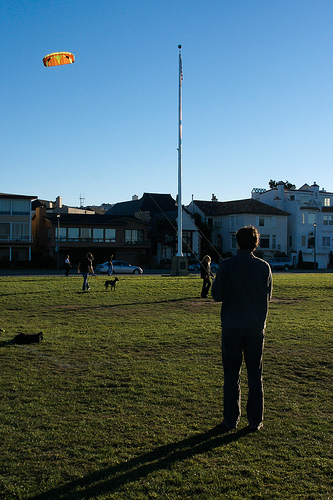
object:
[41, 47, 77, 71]
orange parachute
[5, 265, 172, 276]
color is on road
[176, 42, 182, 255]
white color pole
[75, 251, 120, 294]
man with dog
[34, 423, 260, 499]
shadow in the ground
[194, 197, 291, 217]
brown roof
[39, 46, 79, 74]
parachute is flying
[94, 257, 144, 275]
silver car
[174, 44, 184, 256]
tall flag pole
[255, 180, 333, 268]
house painted white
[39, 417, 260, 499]
shadow of legs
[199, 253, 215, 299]
person flying a kite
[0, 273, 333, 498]
field of grass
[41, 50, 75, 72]
flying a kite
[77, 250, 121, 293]
walking pet dog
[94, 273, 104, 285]
orange leash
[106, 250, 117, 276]
person walking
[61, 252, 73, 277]
person is walking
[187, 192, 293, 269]
white house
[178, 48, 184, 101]
american flag flat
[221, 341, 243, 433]
person's legs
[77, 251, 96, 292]
woman walking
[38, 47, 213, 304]
man flying a kite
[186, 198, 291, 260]
white apartment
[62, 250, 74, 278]
man walking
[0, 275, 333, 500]
freshly cut grass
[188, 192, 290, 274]
apartment buildings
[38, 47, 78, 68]
bright orange kite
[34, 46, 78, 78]
stars and stripes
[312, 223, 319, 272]
street light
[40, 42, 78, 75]
flying the kite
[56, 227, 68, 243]
five windows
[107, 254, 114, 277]
someone near the car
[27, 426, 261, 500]
shadow is behind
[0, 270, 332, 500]
grass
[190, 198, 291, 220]
roof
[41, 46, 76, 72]
parachute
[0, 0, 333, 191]
sky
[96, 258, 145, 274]
car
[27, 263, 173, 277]
road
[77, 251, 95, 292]
man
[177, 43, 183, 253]
flag pole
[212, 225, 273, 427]
person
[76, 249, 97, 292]
person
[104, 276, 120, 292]
dog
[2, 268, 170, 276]
street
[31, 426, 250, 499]
shadow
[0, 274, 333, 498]
park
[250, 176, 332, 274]
apartments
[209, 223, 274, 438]
man